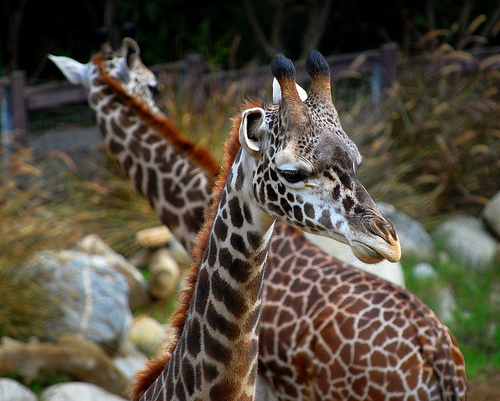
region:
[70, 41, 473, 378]
a giraffe in the background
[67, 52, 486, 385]
two giraffes standing up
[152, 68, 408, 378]
a giraffe walking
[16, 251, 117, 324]
a rock in the field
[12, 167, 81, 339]
brown weeds in the field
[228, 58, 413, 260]
the face of the giraffe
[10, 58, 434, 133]
a wooden fence in the background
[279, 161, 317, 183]
the eye of the giraffe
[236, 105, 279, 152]
the ear of the giraffe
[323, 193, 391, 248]
the mouth of the giraffe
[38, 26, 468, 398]
the two giraffes standing together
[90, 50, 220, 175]
the mane on the giraffe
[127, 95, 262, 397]
the mane on the giraffe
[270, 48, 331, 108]
the horns on the giraffe's head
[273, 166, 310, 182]
the eye on the giraffe's face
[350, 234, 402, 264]
the mouth of the giraffe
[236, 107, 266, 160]
the ear on the giraffe's head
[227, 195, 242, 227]
the brown spot on the giraffe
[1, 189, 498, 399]
the large rocks in the background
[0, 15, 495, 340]
the tall grass behind the rocks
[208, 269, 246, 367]
giraffe with white and brown spots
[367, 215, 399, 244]
nose of the giraffe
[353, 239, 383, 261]
closed mouth of giraffe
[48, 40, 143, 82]
ear of the giraffe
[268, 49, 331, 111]
small horn on head of giraffe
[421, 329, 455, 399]
Tail of the giraffe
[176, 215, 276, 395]
long neck of the giraffe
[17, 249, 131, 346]
rocks lying at background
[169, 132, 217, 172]
orange and brown hair over neck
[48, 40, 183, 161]
giraffe with bend neck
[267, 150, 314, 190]
eye of a giraffe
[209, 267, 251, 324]
brown spot on a giraffe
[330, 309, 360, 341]
brown spot on a giraffe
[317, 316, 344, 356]
brown spot on a giraffe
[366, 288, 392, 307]
brown spot on a giraffe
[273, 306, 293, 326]
brown spot on a giraffe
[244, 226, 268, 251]
brown spot on a giraffe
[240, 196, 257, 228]
brown spot on a giraffe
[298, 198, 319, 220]
brown spot on a giraffe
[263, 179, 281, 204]
brown spot on a giraffe